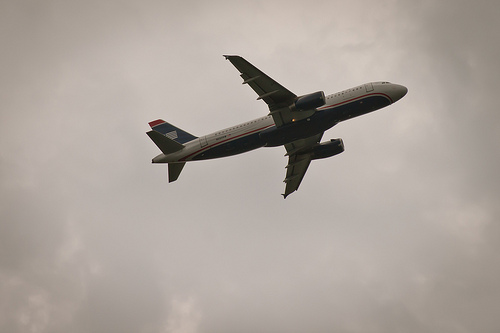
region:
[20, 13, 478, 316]
airplane against gray overcast sky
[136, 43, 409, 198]
white plane with red stripe around blue underside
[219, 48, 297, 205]
pointed cylinders under both wings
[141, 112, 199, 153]
red stripe over blue and white tail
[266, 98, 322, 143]
small yellow light under plane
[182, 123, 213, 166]
rear door on side of plane before tail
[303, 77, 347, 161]
forward-facing curved engines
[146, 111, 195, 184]
small flared wings under tail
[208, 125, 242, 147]
writing under windows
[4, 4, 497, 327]
the sky is gray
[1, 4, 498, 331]
overcast clouds in the sky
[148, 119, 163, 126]
red tip on the tail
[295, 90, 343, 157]
two engines on the wings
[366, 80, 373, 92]
the door is closed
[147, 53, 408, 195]
the plane is in the air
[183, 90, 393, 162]
red stripe on the plane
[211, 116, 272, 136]
windows for passengers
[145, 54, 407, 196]
a commercial airplane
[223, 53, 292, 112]
wing on the plane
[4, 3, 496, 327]
cloud cover in sky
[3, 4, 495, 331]
light in daytime sky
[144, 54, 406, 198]
bottom of flying plane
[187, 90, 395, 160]
red line on plane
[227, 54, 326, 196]
underside of two wings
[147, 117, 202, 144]
red tip on tail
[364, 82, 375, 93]
door on side of plane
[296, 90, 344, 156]
two jet engines of plane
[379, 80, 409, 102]
nose on front of plane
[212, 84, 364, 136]
windows on plane body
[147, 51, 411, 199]
a plane in the sky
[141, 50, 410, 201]
a red white and blue plane in the sky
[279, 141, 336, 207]
a left wing on a plane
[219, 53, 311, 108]
a right wing on a plane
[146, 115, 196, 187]
a tail of a air plane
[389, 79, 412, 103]
the nose of a plane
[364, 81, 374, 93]
a air planes door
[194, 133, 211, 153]
a planes back door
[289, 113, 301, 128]
a light on the plane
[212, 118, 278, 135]
a row of windows on a plane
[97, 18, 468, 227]
a plane in air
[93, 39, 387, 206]
a plane flying in air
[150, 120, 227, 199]
back part of the plane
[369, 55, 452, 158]
front part of the plane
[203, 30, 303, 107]
wing of the plane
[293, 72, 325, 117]
side wing of the plane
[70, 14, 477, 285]
a big plane near to sky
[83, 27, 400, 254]
a big plane near to clouds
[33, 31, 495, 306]
a beautiful view of sky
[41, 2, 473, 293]
a clear view of sky